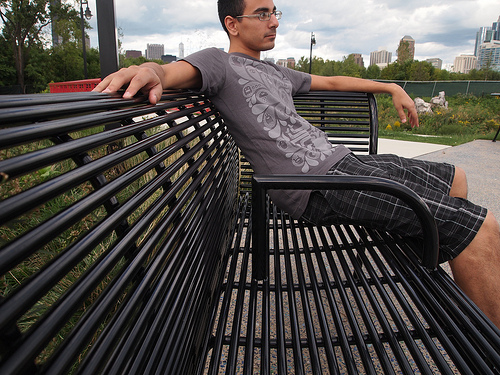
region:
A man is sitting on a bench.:
[88, 10, 494, 371]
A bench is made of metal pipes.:
[0, 91, 495, 371]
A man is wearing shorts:
[302, 142, 482, 257]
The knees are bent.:
[445, 165, 495, 330]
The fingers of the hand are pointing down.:
[390, 85, 425, 125]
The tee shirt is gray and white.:
[177, 46, 347, 216]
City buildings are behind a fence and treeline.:
[276, 20, 496, 102]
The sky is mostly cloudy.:
[20, 0, 495, 70]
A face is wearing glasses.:
[216, 0, 286, 57]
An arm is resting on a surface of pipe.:
[86, 61, 201, 101]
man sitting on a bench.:
[99, 0, 498, 277]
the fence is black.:
[1, 63, 498, 368]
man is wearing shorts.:
[298, 128, 485, 263]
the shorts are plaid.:
[298, 140, 485, 257]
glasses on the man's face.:
[241, 9, 288, 22]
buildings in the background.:
[129, 10, 498, 79]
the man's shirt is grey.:
[179, 38, 355, 208]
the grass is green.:
[369, 85, 498, 145]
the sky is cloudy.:
[41, 2, 498, 68]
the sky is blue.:
[114, 2, 499, 79]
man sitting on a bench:
[183, 0, 491, 275]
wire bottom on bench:
[307, 293, 333, 353]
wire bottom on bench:
[343, 320, 371, 355]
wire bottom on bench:
[375, 308, 395, 345]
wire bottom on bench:
[412, 323, 431, 350]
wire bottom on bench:
[261, 300, 269, 348]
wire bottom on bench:
[246, 305, 258, 348]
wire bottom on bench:
[222, 303, 235, 348]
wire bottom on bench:
[205, 307, 228, 346]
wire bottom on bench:
[140, 238, 162, 262]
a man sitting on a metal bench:
[0, 0, 497, 372]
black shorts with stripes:
[298, 144, 485, 265]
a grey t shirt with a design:
[177, 45, 353, 216]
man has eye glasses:
[231, 8, 284, 24]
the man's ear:
[220, 12, 240, 39]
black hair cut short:
[219, 2, 248, 35]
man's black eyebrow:
[251, 6, 269, 14]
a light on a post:
[309, 30, 316, 70]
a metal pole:
[94, 0, 120, 154]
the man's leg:
[339, 157, 498, 329]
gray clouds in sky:
[86, 1, 491, 54]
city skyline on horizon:
[122, 26, 497, 69]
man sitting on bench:
[8, 0, 498, 374]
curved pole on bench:
[253, 173, 436, 272]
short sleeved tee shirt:
[181, 49, 341, 209]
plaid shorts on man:
[303, 149, 485, 263]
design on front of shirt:
[231, 52, 331, 164]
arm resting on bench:
[304, 69, 418, 125]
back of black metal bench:
[2, 97, 235, 372]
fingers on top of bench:
[98, 71, 160, 104]